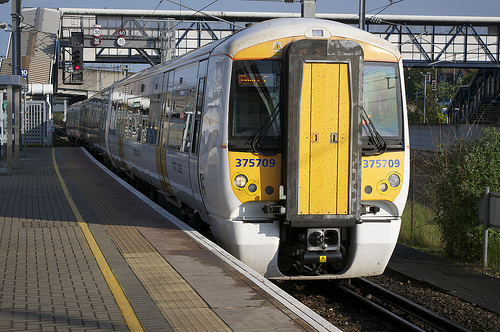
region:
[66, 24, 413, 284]
it is a electric train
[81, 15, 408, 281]
white with yellow color train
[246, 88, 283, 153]
it is glass wiper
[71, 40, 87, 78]
it is signal board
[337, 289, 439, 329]
it is railway track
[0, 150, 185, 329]
it is a platform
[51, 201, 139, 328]
yellow line on the platform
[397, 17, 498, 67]
it is a flyover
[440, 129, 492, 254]
green plant nearby train track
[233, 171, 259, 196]
it is train head light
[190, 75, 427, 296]
this is a train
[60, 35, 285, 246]
the train is yellow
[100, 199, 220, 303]
this is a platform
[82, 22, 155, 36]
this is a bridge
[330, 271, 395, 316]
this is a track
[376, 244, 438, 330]
the track is made of steel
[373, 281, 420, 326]
the track is metal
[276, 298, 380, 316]
the track has rust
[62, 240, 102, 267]
this is some cobblestone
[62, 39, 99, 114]
this is a red light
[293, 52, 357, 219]
door on train car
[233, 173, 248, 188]
light on train car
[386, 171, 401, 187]
light on train car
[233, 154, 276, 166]
train number on car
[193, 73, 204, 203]
door on train car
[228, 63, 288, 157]
window on train car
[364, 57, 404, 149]
window on train car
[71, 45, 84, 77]
train signal light on pole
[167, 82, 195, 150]
window on train car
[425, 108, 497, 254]
bush next to train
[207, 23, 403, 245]
front of train is yellow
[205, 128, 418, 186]
blue numbers on train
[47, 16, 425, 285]
the train is white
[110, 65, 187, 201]
train doors are yellow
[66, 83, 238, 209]
reflection on the train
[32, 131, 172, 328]
yellow line on platform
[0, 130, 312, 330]
the platform is brown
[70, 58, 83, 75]
red light on sign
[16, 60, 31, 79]
blue and white sign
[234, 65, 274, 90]
lights on the train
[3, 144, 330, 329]
yellow and white line on platform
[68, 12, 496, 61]
covered walkway over railroad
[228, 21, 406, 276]
white and yellow front of train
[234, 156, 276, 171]
blue number on yellow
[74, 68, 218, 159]
side of train at platform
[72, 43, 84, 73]
glowing red light above platform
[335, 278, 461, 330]
metal rails of track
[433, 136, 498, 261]
green leaves on bush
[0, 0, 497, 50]
blue of daytime sky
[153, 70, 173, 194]
yellow double doors on train